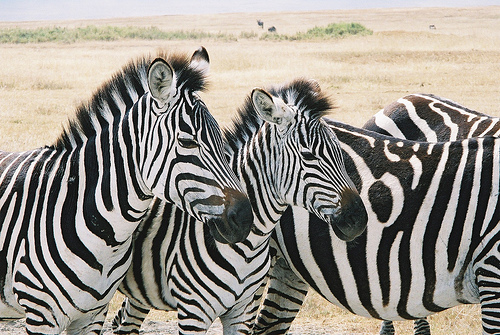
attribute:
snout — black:
[203, 183, 254, 245]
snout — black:
[327, 185, 365, 240]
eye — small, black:
[300, 149, 319, 162]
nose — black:
[199, 204, 257, 243]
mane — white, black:
[52, 49, 203, 147]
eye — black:
[175, 131, 203, 150]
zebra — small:
[120, 77, 367, 332]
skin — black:
[276, 77, 332, 119]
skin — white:
[407, 180, 433, 318]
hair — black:
[91, 73, 121, 93]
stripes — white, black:
[433, 136, 498, 232]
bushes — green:
[317, 21, 381, 68]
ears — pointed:
[159, 60, 215, 103]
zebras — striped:
[49, 5, 492, 302]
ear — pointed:
[104, 43, 185, 86]